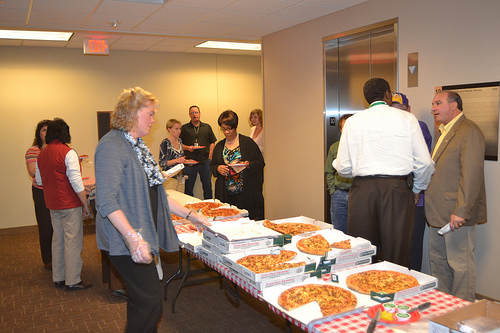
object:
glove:
[124, 227, 155, 265]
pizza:
[275, 282, 357, 314]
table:
[164, 189, 477, 331]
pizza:
[344, 268, 418, 297]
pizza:
[233, 248, 305, 275]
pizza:
[296, 235, 352, 258]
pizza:
[262, 217, 320, 237]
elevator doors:
[337, 29, 397, 132]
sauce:
[395, 311, 413, 320]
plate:
[367, 301, 421, 326]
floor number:
[329, 116, 337, 127]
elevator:
[323, 17, 403, 221]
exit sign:
[82, 37, 110, 57]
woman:
[34, 117, 91, 292]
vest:
[35, 140, 82, 209]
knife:
[366, 309, 383, 332]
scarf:
[120, 126, 168, 188]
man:
[420, 91, 487, 302]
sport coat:
[421, 114, 487, 228]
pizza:
[202, 206, 244, 218]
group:
[323, 78, 491, 299]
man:
[332, 78, 435, 268]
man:
[389, 92, 432, 271]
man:
[323, 114, 352, 235]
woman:
[93, 87, 181, 332]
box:
[220, 245, 316, 283]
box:
[331, 259, 439, 305]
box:
[285, 226, 370, 262]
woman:
[25, 120, 63, 271]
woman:
[210, 109, 267, 219]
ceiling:
[0, 1, 369, 58]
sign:
[406, 51, 419, 88]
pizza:
[183, 201, 221, 212]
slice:
[326, 238, 351, 252]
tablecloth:
[183, 248, 472, 331]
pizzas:
[169, 213, 182, 223]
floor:
[1, 223, 302, 331]